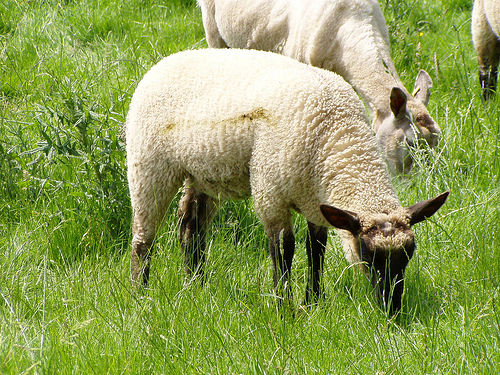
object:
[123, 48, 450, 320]
sheep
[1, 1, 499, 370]
grass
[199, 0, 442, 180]
sheep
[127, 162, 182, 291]
leg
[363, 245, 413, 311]
face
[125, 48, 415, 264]
wool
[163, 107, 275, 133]
stain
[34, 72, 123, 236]
plant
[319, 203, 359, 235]
ear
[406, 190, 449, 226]
ear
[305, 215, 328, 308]
leg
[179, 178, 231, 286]
leg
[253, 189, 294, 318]
leg